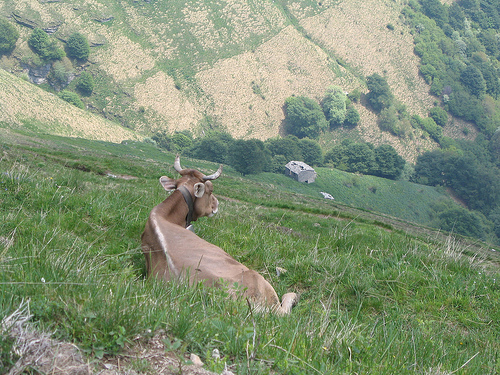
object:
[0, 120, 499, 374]
grass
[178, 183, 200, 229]
collar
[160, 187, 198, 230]
neck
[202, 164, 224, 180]
horn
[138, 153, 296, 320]
cow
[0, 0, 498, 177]
hillside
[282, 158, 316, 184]
house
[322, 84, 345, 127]
tree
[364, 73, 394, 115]
tree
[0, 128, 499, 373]
field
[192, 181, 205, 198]
ear